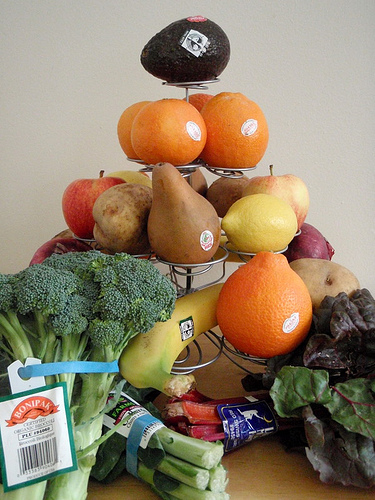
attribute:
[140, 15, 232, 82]
avocado — top, green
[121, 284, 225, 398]
banana — yellow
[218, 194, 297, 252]
lemon — yellow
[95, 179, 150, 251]
potato — white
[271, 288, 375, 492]
lettuce — red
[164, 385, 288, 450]
rhubarb — bunch, red, bundle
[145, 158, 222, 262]
pear — brown, tan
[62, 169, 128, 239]
apple — red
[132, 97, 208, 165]
orange — bright, round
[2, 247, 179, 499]
broccoli — green, bunch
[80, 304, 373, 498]
table — wood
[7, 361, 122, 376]
rubberband — blue